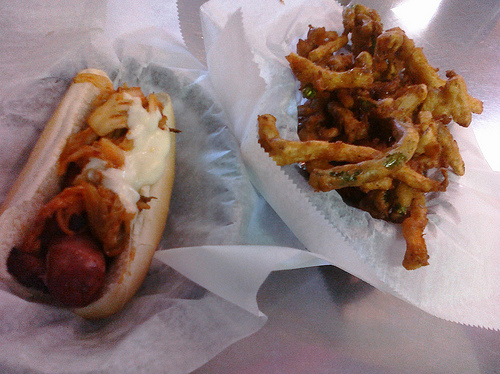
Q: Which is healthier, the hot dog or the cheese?
A: The cheese is healthier than the hot dog.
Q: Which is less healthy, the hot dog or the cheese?
A: The hot dog is less healthy than the cheese.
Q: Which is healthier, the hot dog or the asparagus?
A: The asparagus is healthier than the hot dog.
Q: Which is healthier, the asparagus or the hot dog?
A: The asparagus is healthier than the hot dog.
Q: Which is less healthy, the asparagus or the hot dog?
A: The hot dog is less healthy than the asparagus.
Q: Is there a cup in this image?
A: No, there are no cups.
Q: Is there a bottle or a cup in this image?
A: No, there are no cups or bottles.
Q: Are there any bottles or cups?
A: No, there are no cups or bottles.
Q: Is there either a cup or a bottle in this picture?
A: No, there are no cups or bottles.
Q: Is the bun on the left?
A: Yes, the bun is on the left of the image.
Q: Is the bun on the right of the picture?
A: No, the bun is on the left of the image.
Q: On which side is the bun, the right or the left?
A: The bun is on the left of the image.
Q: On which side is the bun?
A: The bun is on the left of the image.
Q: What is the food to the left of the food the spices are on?
A: The food is a bun.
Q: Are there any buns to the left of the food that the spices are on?
A: Yes, there is a bun to the left of the food.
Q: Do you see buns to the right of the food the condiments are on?
A: No, the bun is to the left of the food.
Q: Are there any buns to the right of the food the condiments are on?
A: No, the bun is to the left of the food.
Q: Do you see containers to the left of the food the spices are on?
A: No, there is a bun to the left of the food.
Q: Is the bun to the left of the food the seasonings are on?
A: Yes, the bun is to the left of the food.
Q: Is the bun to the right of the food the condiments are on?
A: No, the bun is to the left of the food.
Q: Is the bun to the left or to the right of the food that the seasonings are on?
A: The bun is to the left of the food.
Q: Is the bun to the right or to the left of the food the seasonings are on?
A: The bun is to the left of the food.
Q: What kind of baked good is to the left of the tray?
A: The food is a bun.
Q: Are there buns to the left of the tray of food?
A: Yes, there is a bun to the left of the tray.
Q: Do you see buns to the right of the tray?
A: No, the bun is to the left of the tray.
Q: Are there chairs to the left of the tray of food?
A: No, there is a bun to the left of the tray.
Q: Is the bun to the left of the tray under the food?
A: Yes, the bun is to the left of the tray.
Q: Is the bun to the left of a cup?
A: No, the bun is to the left of the tray.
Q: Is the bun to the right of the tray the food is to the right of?
A: No, the bun is to the left of the tray.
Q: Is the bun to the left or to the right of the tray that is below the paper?
A: The bun is to the left of the tray.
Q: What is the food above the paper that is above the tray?
A: The food is a bun.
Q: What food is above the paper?
A: The food is a bun.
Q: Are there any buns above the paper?
A: Yes, there is a bun above the paper.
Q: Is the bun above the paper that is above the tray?
A: Yes, the bun is above the paper.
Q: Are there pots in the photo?
A: No, there are no pots.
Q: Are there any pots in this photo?
A: No, there are no pots.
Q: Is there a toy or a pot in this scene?
A: No, there are no pots or toys.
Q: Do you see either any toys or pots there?
A: No, there are no pots or toys.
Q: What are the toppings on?
A: The toppings are on the hot dog.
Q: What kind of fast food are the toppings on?
A: The toppings are on the hot dog.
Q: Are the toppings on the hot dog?
A: Yes, the toppings are on the hot dog.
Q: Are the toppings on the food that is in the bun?
A: Yes, the toppings are on the hot dog.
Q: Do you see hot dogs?
A: Yes, there is a hot dog.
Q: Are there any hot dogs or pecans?
A: Yes, there is a hot dog.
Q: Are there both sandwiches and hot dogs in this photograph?
A: Yes, there are both a hot dog and a sandwich.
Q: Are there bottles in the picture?
A: No, there are no bottles.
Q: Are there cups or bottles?
A: No, there are no bottles or cups.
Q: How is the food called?
A: The food is a hot dog.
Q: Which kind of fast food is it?
A: The food is a hot dog.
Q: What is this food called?
A: This is a hot dog.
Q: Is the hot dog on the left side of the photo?
A: Yes, the hot dog is on the left of the image.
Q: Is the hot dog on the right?
A: No, the hot dog is on the left of the image.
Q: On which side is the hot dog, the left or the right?
A: The hot dog is on the left of the image.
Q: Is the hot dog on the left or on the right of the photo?
A: The hot dog is on the left of the image.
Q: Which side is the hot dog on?
A: The hot dog is on the left of the image.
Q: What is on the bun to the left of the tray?
A: The hot dog is on the bun.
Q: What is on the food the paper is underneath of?
A: The hot dog is on the bun.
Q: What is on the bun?
A: The hot dog is on the bun.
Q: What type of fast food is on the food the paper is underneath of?
A: The food is a hot dog.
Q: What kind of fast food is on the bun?
A: The food is a hot dog.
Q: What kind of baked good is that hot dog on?
A: The hot dog is on the bun.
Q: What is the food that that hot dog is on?
A: The food is a bun.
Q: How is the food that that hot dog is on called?
A: The food is a bun.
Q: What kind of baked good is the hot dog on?
A: The hot dog is on the bun.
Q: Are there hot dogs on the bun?
A: Yes, there is a hot dog on the bun.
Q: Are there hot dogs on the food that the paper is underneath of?
A: Yes, there is a hot dog on the bun.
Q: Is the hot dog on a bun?
A: Yes, the hot dog is on a bun.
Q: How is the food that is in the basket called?
A: The food is a hot dog.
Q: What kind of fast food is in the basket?
A: The food is a hot dog.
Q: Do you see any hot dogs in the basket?
A: Yes, there is a hot dog in the basket.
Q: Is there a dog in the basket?
A: No, there is a hot dog in the basket.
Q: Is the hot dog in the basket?
A: Yes, the hot dog is in the basket.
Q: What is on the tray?
A: The hot dog is on the tray.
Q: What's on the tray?
A: The hot dog is on the tray.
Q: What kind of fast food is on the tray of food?
A: The food is a hot dog.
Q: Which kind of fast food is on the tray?
A: The food is a hot dog.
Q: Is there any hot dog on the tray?
A: Yes, there is a hot dog on the tray.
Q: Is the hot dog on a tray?
A: Yes, the hot dog is on a tray.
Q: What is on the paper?
A: The hot dog is on the paper.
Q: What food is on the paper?
A: The food is a hot dog.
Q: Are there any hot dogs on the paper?
A: Yes, there is a hot dog on the paper.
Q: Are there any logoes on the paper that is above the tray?
A: No, there is a hot dog on the paper.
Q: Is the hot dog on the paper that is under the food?
A: Yes, the hot dog is on the paper.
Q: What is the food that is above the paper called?
A: The food is a hot dog.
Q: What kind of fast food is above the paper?
A: The food is a hot dog.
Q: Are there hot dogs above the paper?
A: Yes, there is a hot dog above the paper.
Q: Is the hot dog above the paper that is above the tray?
A: Yes, the hot dog is above the paper.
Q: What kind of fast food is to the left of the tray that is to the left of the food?
A: The food is a hot dog.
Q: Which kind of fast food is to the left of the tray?
A: The food is a hot dog.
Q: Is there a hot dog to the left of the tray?
A: Yes, there is a hot dog to the left of the tray.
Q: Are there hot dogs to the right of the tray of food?
A: No, the hot dog is to the left of the tray.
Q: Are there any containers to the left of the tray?
A: No, there is a hot dog to the left of the tray.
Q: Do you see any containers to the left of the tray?
A: No, there is a hot dog to the left of the tray.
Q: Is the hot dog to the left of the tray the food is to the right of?
A: Yes, the hot dog is to the left of the tray.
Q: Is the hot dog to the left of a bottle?
A: No, the hot dog is to the left of the tray.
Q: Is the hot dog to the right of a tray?
A: No, the hot dog is to the left of a tray.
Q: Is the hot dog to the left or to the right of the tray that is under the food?
A: The hot dog is to the left of the tray.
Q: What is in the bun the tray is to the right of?
A: The hot dog is in the bun.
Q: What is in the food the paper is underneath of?
A: The hot dog is in the bun.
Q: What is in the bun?
A: The hot dog is in the bun.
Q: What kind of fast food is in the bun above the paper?
A: The food is a hot dog.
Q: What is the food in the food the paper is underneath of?
A: The food is a hot dog.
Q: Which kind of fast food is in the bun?
A: The food is a hot dog.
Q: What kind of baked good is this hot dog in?
A: The hot dog is in the bun.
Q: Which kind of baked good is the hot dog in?
A: The hot dog is in the bun.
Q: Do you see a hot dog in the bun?
A: Yes, there is a hot dog in the bun.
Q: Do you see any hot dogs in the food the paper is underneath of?
A: Yes, there is a hot dog in the bun.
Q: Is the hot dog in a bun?
A: Yes, the hot dog is in a bun.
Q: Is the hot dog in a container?
A: No, the hot dog is in a bun.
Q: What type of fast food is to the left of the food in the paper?
A: The food is a hot dog.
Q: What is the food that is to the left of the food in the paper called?
A: The food is a hot dog.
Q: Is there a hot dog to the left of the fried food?
A: Yes, there is a hot dog to the left of the food.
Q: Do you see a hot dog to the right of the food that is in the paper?
A: No, the hot dog is to the left of the food.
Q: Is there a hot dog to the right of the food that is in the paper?
A: No, the hot dog is to the left of the food.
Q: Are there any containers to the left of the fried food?
A: No, there is a hot dog to the left of the food.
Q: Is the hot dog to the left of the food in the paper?
A: Yes, the hot dog is to the left of the food.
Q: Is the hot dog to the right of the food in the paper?
A: No, the hot dog is to the left of the food.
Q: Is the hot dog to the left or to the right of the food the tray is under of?
A: The hot dog is to the left of the food.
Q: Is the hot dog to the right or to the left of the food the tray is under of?
A: The hot dog is to the left of the food.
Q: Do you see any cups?
A: No, there are no cups.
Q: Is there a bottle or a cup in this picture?
A: No, there are no cups or bottles.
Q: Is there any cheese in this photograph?
A: Yes, there is cheese.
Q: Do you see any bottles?
A: No, there are no bottles.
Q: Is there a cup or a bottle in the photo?
A: No, there are no bottles or cups.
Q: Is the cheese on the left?
A: Yes, the cheese is on the left of the image.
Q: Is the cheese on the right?
A: No, the cheese is on the left of the image.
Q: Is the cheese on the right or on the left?
A: The cheese is on the left of the image.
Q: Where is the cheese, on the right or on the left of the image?
A: The cheese is on the left of the image.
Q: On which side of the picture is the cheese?
A: The cheese is on the left of the image.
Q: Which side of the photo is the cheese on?
A: The cheese is on the left of the image.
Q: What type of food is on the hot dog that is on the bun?
A: The food is cheese.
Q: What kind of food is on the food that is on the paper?
A: The food is cheese.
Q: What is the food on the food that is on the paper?
A: The food is cheese.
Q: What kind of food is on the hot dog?
A: The food is cheese.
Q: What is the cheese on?
A: The cheese is on the hot dog.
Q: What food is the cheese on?
A: The cheese is on the hot dog.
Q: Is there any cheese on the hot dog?
A: Yes, there is cheese on the hot dog.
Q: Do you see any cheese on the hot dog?
A: Yes, there is cheese on the hot dog.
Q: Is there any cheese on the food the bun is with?
A: Yes, there is cheese on the hot dog.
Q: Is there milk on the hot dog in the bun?
A: No, there is cheese on the hot dog.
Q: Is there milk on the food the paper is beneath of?
A: No, there is cheese on the hot dog.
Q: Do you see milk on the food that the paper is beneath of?
A: No, there is cheese on the hot dog.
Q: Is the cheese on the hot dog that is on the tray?
A: Yes, the cheese is on the hot dog.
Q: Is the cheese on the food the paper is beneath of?
A: Yes, the cheese is on the hot dog.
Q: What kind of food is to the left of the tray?
A: The food is cheese.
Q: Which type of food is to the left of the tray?
A: The food is cheese.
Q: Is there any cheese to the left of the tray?
A: Yes, there is cheese to the left of the tray.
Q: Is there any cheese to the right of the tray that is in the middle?
A: No, the cheese is to the left of the tray.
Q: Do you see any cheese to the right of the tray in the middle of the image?
A: No, the cheese is to the left of the tray.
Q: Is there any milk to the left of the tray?
A: No, there is cheese to the left of the tray.